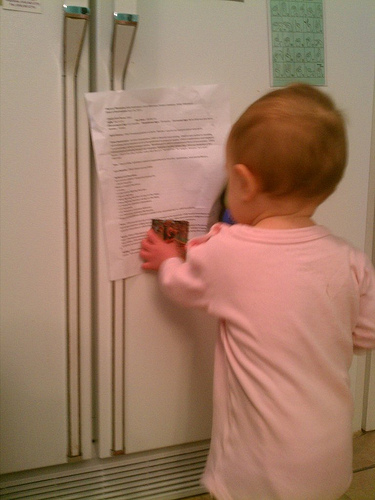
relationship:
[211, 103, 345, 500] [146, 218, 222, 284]
baby has picture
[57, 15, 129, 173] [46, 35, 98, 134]
door has handles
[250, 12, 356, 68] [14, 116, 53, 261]
calendar on wall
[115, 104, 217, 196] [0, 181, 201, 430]
paper on refrigerator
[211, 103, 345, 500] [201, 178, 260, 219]
baby has pacifier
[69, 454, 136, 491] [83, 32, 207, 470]
vents on fridge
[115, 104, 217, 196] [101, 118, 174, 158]
paper has writing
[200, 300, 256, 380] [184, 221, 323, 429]
wrinkles in shirt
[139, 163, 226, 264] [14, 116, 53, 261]
pictures on wall